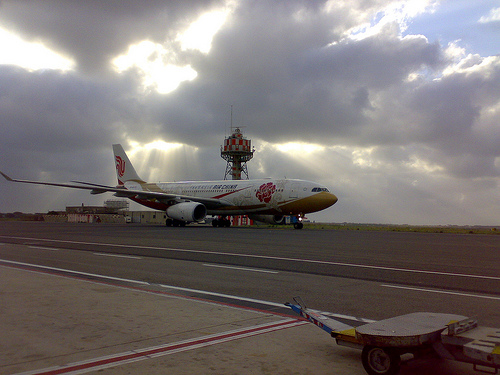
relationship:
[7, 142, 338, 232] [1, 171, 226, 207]
airplane has wing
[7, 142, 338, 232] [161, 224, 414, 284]
airplane on tarmac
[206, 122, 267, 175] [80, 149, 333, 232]
tower by plane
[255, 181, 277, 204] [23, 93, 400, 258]
brand on plane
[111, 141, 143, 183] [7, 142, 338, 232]
tail of airplane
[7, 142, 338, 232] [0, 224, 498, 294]
airplane on runway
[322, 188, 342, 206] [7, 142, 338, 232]
nose of airplane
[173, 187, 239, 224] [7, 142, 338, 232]
engine on airplane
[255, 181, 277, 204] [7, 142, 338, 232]
brand on airplane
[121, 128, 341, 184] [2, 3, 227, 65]
light shines through cloud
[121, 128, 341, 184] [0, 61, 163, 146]
light shines through cloud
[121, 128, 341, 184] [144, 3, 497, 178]
light shines through cloud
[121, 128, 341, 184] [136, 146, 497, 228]
light shines through cloud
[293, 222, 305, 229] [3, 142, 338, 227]
front wheel of jet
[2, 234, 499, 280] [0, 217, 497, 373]
strip marking on runway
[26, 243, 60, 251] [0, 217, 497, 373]
strip marking on runway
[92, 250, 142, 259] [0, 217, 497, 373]
strip marking on runway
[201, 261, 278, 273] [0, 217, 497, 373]
strip marking on runway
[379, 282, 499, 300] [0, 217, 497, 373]
strip marking on runway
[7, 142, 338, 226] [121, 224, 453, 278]
airplane on ground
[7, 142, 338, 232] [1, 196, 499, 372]
airplane on airfield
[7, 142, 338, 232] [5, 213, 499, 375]
airplane on tarmark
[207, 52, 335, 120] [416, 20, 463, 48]
clouds in sky